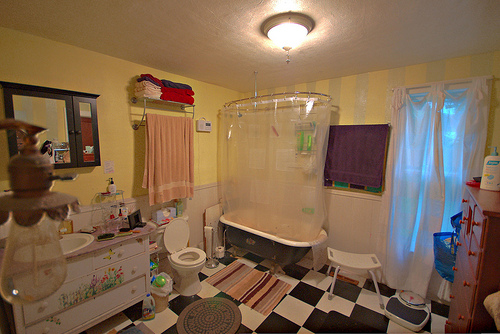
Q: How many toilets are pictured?
A: One.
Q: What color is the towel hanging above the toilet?
A: Peach.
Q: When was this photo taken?
A: Daytime.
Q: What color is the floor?
A: Checkerboard.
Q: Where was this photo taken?
A: In a bathroom.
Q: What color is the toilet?
A: White.